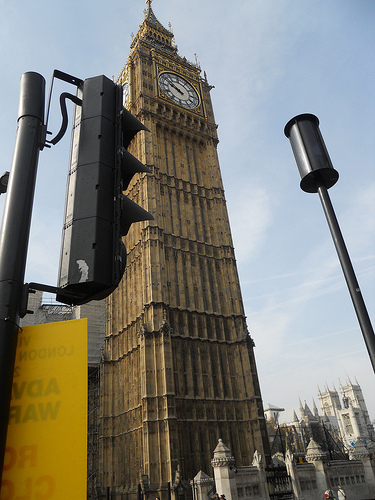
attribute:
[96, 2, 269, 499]
tower — brown, large, big ben, in London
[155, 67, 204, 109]
clock — black, white, numbered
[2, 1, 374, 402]
sky — blue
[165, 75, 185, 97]
hands — black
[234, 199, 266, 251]
cloud — white